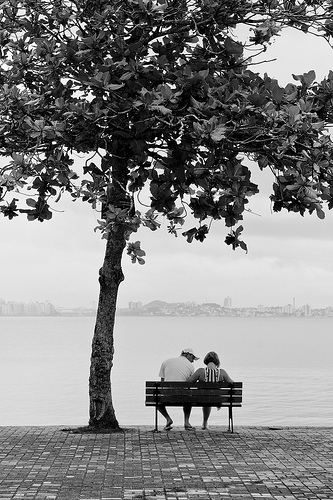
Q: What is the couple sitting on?
A: Bench.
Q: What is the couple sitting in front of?
A: Water.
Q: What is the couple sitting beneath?
A: A tree.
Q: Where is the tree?
A: By the water.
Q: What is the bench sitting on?
A: Pavement.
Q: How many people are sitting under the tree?
A: Two.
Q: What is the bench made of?
A: Wood.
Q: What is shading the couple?
A: A tree.